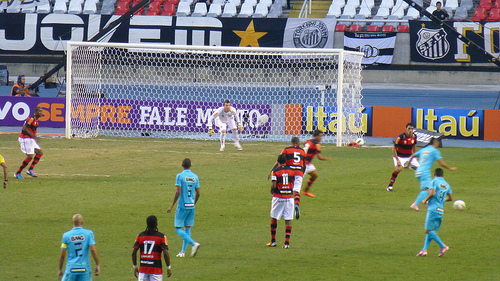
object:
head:
[145, 214, 162, 228]